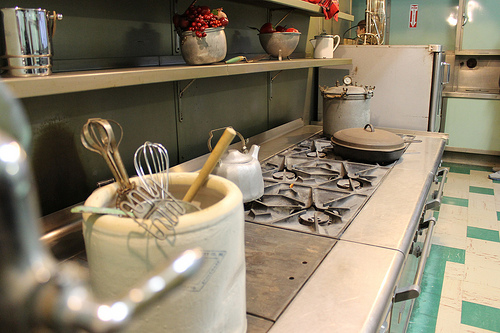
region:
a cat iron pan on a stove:
[325, 146, 407, 167]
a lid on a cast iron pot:
[329, 122, 408, 151]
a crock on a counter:
[77, 175, 250, 330]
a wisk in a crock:
[131, 138, 171, 209]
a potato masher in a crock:
[118, 173, 191, 226]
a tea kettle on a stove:
[205, 125, 265, 206]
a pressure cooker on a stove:
[315, 75, 375, 140]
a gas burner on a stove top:
[275, 185, 350, 230]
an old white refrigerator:
[317, 41, 450, 131]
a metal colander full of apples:
[256, 21, 301, 61]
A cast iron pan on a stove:
[332, 123, 404, 163]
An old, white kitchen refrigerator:
[315, 45, 445, 132]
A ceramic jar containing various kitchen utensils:
[85, 173, 246, 330]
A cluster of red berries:
[175, 10, 227, 36]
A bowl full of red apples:
[256, 23, 298, 58]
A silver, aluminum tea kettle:
[205, 126, 260, 196]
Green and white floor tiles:
[405, 165, 496, 330]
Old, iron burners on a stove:
[243, 132, 385, 241]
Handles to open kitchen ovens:
[392, 167, 448, 303]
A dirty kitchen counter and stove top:
[222, 125, 442, 330]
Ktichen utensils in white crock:
[72, 115, 250, 332]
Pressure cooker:
[322, 76, 373, 140]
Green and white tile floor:
[444, 161, 498, 331]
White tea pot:
[207, 124, 264, 202]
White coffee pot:
[310, 28, 339, 56]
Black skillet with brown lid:
[332, 121, 423, 165]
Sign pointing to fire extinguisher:
[408, 2, 418, 27]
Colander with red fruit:
[255, 17, 301, 58]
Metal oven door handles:
[392, 163, 449, 302]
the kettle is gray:
[206, 125, 271, 224]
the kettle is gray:
[199, 127, 264, 215]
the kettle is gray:
[200, 119, 277, 230]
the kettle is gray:
[188, 120, 280, 234]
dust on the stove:
[265, 134, 377, 248]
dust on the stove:
[260, 138, 337, 233]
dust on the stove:
[265, 150, 365, 252]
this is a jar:
[53, 118, 260, 329]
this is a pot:
[176, 18, 232, 72]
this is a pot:
[261, 11, 322, 66]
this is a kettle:
[212, 134, 278, 204]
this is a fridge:
[344, 34, 464, 168]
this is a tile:
[454, 291, 492, 328]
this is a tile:
[456, 245, 498, 298]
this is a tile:
[466, 181, 497, 209]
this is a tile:
[472, 188, 497, 235]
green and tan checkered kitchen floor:
[404, 153, 497, 331]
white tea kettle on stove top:
[203, 120, 267, 205]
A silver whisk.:
[130, 136, 175, 193]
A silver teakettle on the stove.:
[213, 124, 266, 208]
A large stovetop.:
[167, 101, 437, 245]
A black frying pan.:
[332, 121, 407, 162]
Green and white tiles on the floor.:
[384, 147, 494, 329]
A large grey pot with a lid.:
[326, 79, 373, 146]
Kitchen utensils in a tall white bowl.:
[79, 108, 257, 310]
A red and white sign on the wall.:
[408, 3, 420, 29]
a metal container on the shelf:
[0, 7, 60, 77]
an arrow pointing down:
[410, 3, 417, 26]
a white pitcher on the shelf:
[309, 28, 340, 56]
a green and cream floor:
[407, 161, 498, 331]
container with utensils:
[82, 174, 247, 331]